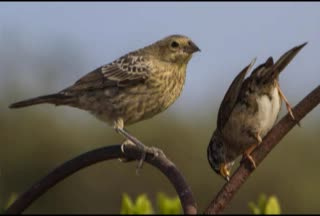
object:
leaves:
[120, 191, 184, 215]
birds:
[7, 34, 307, 183]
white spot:
[179, 187, 189, 196]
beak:
[193, 44, 201, 53]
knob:
[213, 191, 232, 205]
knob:
[161, 159, 171, 173]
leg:
[256, 134, 262, 147]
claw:
[136, 147, 165, 172]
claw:
[287, 104, 299, 126]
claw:
[243, 153, 256, 170]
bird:
[8, 35, 202, 175]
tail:
[9, 93, 71, 109]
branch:
[203, 87, 320, 216]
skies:
[2, 0, 320, 127]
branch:
[1, 144, 196, 216]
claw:
[120, 141, 125, 154]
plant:
[0, 87, 319, 216]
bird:
[206, 43, 309, 183]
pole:
[0, 86, 320, 216]